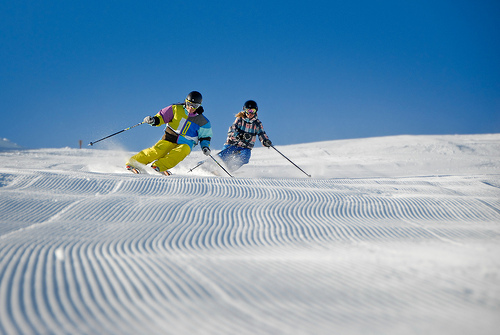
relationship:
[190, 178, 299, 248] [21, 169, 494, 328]
lines in snow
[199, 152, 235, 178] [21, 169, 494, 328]
pole in snow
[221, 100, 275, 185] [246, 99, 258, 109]
person has hat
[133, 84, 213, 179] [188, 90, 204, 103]
person has hat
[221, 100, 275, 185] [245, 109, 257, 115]
person has goggles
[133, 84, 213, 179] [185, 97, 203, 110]
person has goggles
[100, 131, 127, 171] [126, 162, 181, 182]
spray from skis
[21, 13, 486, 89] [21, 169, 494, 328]
sky above snow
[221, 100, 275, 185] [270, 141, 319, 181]
person has pole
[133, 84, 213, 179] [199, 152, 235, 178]
person has pole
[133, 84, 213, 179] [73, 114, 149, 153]
person has pole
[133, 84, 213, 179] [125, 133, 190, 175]
person has snow pants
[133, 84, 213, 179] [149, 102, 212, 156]
person has jacket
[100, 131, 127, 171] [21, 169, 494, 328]
spray of snow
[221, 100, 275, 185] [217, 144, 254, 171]
person has pants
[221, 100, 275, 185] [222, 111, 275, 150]
person has jacket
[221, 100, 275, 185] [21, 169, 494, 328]
person on snow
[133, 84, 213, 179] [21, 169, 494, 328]
person on snow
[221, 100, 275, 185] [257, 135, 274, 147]
person has glove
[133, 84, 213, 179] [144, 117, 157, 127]
person has glove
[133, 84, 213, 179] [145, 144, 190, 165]
person has legs